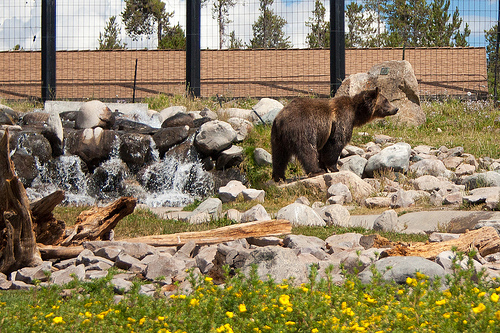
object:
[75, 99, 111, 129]
rocks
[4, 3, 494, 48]
sky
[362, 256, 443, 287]
rock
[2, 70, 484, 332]
field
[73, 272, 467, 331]
flower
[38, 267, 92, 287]
large rock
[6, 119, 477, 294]
enclosure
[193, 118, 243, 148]
large rock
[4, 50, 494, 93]
wall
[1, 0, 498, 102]
cage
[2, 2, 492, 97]
fence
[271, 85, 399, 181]
bear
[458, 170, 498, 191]
rock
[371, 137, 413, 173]
snowrock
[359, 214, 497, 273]
log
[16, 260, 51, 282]
rocks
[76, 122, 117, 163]
rock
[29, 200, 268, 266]
log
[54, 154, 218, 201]
waterfall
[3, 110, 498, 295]
rock design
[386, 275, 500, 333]
yellow flowers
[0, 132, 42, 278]
tree stump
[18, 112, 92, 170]
stone